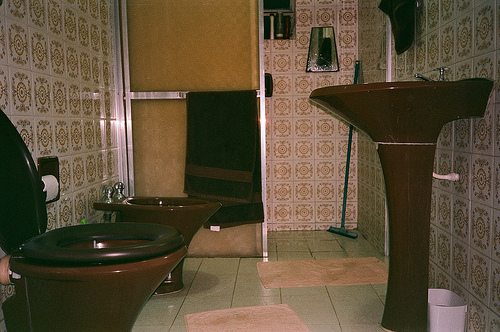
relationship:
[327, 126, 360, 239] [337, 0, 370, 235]
broom in corner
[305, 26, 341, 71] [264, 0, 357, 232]
mirror on wall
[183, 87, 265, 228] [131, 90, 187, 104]
towel on rack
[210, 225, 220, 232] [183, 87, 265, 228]
tag on towel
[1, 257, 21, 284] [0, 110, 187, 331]
pipe behind toilet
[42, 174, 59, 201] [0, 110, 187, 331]
toilet paper near toilet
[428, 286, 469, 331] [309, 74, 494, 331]
trash can under sink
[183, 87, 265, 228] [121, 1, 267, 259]
towel hanging on shower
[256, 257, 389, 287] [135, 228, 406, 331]
bath mat on floor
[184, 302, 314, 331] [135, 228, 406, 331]
rug on floor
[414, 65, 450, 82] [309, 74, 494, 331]
tap on sink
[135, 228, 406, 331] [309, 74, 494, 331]
floor under sink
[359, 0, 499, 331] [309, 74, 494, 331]
wall behind sink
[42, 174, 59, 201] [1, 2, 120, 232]
toilet paper on wall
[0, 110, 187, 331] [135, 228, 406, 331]
toilet on floor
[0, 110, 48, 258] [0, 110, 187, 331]
lid on toilet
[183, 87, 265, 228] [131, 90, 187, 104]
towel hanging on rack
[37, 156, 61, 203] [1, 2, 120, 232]
toilet paper holder on wall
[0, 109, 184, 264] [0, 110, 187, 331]
toilet seat on toilet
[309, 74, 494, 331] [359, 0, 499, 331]
sink attached to wall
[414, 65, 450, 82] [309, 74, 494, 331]
tap over sink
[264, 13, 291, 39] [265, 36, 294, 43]
toiletries on holder